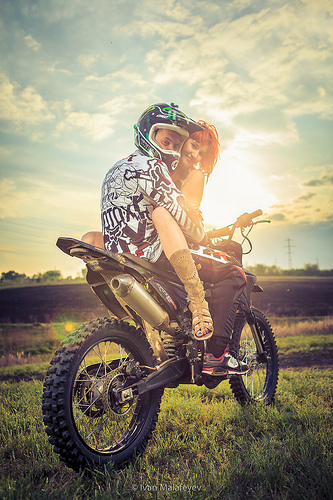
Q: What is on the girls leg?
A: A boot.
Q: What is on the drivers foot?
A: A black and white shoe.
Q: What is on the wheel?
A: A chain.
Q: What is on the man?
A: A black and white shirt.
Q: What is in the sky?
A: Gray blue clouds.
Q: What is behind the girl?
A: Handle bars.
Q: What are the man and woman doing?
A: Looking.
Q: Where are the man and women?
A: Motorbike.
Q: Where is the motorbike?
A: Grass.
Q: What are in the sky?
A: Clouds.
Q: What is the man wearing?
A: Shirt.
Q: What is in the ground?
A: Grass.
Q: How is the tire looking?
A: Large.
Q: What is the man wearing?
A: Helmet.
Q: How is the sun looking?
A: Bright.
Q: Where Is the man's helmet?
A: On his head.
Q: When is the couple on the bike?
A: Daytime.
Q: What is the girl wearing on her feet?
A: Boots.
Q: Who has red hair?
A: The girl.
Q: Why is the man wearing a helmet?
A: Safety.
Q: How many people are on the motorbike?
A: Two.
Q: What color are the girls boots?
A: Tan.